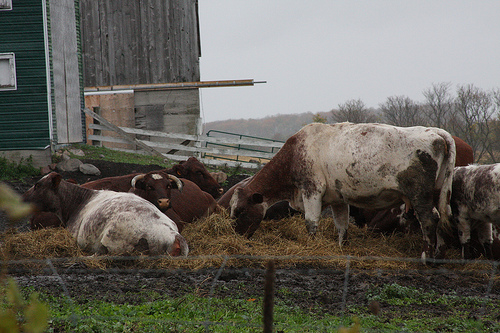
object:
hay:
[1, 203, 499, 280]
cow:
[227, 121, 456, 265]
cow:
[20, 169, 190, 258]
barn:
[0, 1, 201, 173]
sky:
[197, 0, 499, 122]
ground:
[1, 145, 500, 332]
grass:
[0, 280, 500, 332]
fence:
[0, 254, 500, 332]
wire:
[0, 255, 499, 331]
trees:
[453, 81, 500, 163]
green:
[0, 0, 43, 147]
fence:
[84, 106, 287, 170]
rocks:
[54, 156, 86, 172]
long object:
[82, 78, 268, 93]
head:
[228, 183, 269, 239]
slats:
[81, 108, 171, 163]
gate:
[130, 85, 199, 160]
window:
[0, 53, 18, 93]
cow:
[128, 170, 228, 233]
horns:
[131, 173, 149, 191]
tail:
[430, 126, 457, 244]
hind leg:
[403, 170, 437, 266]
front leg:
[301, 169, 327, 241]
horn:
[165, 172, 183, 191]